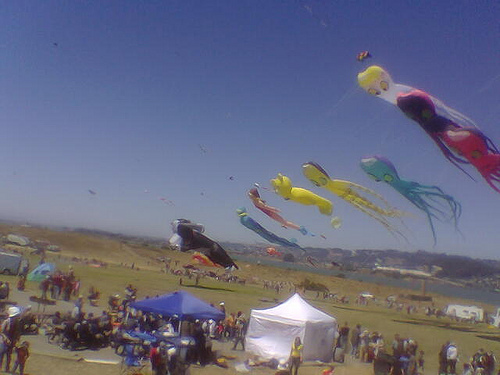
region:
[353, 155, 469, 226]
blue octopus shaped kite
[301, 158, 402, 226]
yellow octopus shaped kite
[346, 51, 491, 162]
three octopus shaped kites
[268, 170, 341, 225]
yellow kite in the air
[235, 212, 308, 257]
kite in the air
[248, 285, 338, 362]
white tent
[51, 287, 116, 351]
group of people sitting on a bench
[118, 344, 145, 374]
blue lawn chair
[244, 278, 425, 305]
people on a field in the distance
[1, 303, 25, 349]
person has white hat on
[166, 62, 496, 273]
Group of ballon kites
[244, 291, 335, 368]
White tent sitting in the field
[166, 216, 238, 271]
Black and white ballon kite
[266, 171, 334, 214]
Yellow balloon kit floating in the air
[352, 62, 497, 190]
Body balloon kite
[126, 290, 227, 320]
Purple canopy tent sitting in the field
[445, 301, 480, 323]
White building in the distance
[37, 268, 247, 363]
Group of people watching the balloon kites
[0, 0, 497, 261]
Kites flying against the blue sky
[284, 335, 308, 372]
Woman wearing a yellow tee shirt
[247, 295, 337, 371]
White square tent in field.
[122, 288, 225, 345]
Blue overhead awning in field.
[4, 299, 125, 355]
Crowd of people in field.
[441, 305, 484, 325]
White camper in field.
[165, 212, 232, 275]
Black kite in mid-air.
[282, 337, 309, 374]
Woman in yellow shirt.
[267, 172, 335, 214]
Yellow cat kite in sky.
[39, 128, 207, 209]
Clear, blue skies.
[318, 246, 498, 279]
Mountainside in background.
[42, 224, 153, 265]
Grassy hillside in distance.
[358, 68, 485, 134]
kite flying the sky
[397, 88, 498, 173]
kite flying the sky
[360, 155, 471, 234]
kite flying the sky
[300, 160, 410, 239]
kite flying the sky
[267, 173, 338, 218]
kite flying the sky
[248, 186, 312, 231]
kite flying the sky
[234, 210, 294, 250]
kite flying the sky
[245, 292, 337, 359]
white tent under kites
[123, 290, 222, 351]
blue tent under kites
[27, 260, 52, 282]
green umbrella in crowd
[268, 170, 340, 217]
yellow cat kite in sky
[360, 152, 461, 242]
blue kite with yellow eyes in sky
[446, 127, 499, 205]
red kite with yellow eyes in sky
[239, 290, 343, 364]
white tent on grassy ground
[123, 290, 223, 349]
blue tent on grassy ground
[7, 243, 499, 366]
grassy ground with many visitors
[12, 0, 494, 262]
slightly misty blue sunny sky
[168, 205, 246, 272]
black and white dog kite in sky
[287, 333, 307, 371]
woman in yellow shirt and gray shorts walking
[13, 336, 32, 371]
small blond child with red shirt